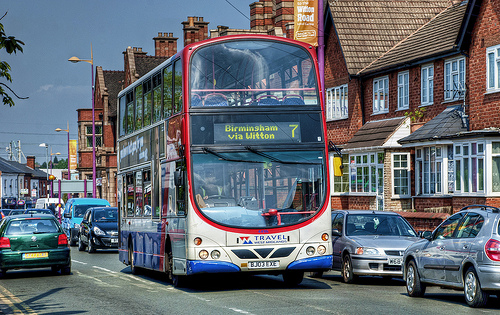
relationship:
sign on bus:
[212, 121, 301, 141] [115, 36, 333, 287]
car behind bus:
[76, 204, 121, 262] [115, 36, 333, 287]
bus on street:
[115, 36, 333, 287] [0, 242, 499, 312]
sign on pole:
[291, 1, 324, 53] [315, 0, 327, 108]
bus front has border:
[188, 42, 357, 248] [181, 32, 329, 232]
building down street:
[0, 144, 85, 238] [0, 242, 499, 312]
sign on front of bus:
[225, 124, 299, 139] [115, 36, 333, 287]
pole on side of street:
[65, 34, 113, 238] [3, 233, 497, 313]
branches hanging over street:
[0, 8, 62, 155] [7, 141, 348, 311]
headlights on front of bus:
[195, 244, 332, 259] [115, 36, 333, 287]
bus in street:
[115, 36, 333, 287] [0, 242, 499, 312]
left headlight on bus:
[317, 232, 329, 242] [115, 36, 333, 287]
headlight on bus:
[187, 234, 209, 246] [115, 36, 333, 287]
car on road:
[0, 213, 71, 274] [0, 241, 499, 313]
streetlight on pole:
[61, 46, 95, 71] [89, 42, 98, 202]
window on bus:
[113, 96, 127, 142] [115, 36, 333, 287]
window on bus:
[192, 46, 322, 108] [115, 36, 333, 287]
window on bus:
[133, 85, 143, 128] [115, 36, 333, 287]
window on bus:
[141, 74, 158, 129] [115, 36, 333, 287]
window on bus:
[162, 59, 173, 119] [115, 36, 333, 287]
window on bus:
[171, 56, 184, 113] [115, 36, 333, 287]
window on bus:
[188, 40, 321, 108] [115, 36, 333, 287]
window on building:
[484, 46, 499, 101] [326, 7, 494, 239]